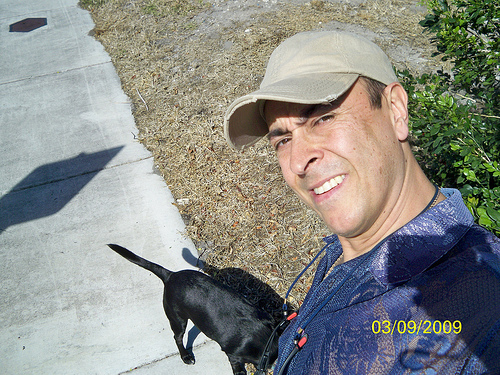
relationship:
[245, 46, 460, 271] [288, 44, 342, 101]
man wearing hat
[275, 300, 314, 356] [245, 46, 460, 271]
sunglasses on man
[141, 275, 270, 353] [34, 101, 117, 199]
dog in street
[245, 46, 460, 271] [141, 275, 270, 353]
man with dog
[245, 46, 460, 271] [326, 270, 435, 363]
man wearing shirt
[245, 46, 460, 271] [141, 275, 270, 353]
man walking dog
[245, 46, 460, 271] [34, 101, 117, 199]
man on street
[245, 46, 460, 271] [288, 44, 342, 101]
man with hat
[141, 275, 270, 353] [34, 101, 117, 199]
dog on street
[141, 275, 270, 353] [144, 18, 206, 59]
dog on grass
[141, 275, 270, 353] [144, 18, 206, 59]
dog in grass